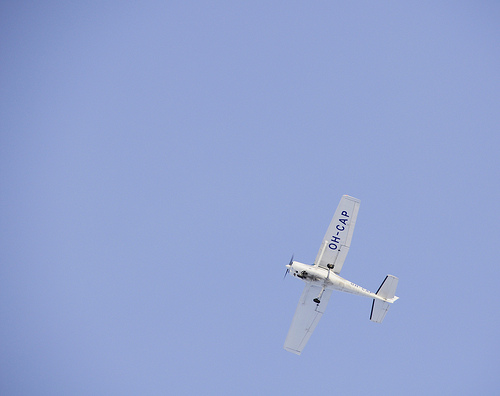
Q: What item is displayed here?
A: An airplane.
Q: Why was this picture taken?
A: To show the beauty of a plane.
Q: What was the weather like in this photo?
A: Clear skies.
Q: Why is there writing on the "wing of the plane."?
A: Name of the company that own the plane.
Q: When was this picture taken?
A: Daylight.